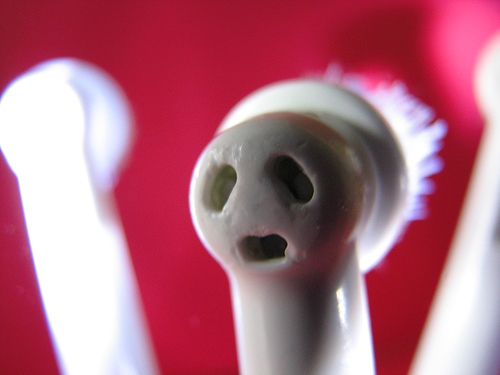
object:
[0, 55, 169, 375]
brush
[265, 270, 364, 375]
shadow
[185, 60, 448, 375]
brush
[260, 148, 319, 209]
hole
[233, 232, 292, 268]
hole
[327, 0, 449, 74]
shadows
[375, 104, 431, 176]
light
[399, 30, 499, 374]
object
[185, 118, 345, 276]
face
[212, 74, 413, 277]
rim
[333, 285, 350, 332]
reflection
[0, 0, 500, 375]
red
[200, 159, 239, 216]
hole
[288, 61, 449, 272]
bristles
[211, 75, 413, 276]
front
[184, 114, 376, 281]
back end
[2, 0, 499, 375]
red cloth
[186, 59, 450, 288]
head